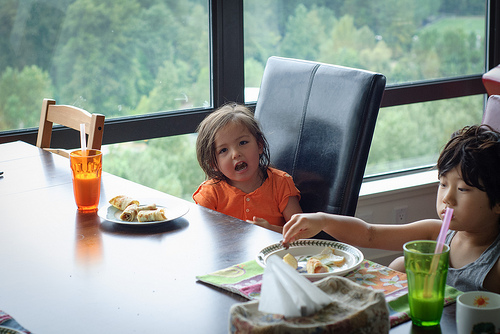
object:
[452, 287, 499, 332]
coffee mug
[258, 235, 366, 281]
plate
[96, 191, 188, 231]
plate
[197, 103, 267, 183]
head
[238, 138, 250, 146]
eye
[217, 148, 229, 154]
eye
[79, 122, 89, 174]
straw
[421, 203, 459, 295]
straw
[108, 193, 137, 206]
pancake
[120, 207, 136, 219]
pancake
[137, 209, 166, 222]
pancake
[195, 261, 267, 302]
placemat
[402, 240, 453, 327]
cup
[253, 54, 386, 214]
chair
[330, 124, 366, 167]
ground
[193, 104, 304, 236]
child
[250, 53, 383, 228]
seat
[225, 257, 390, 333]
box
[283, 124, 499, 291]
boy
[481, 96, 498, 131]
chair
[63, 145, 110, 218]
drink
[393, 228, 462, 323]
drink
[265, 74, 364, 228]
reflection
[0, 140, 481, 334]
table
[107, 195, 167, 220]
finger foods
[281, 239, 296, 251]
finger foods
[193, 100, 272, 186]
hair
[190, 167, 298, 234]
shirt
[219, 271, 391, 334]
cover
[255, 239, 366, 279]
dinner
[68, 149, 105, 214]
glass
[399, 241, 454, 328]
glass